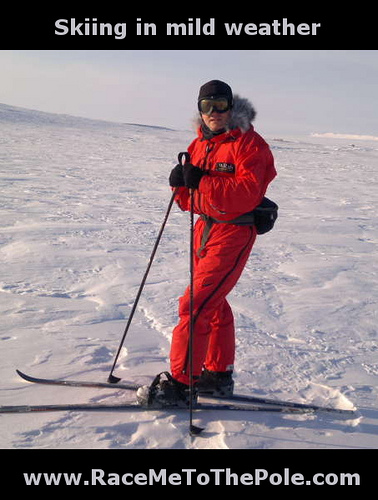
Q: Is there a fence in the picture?
A: No, there are no fences.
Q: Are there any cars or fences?
A: No, there are no fences or cars.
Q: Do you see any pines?
A: No, there are no pines.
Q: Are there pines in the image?
A: No, there are no pines.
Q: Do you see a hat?
A: Yes, there is a hat.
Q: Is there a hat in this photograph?
A: Yes, there is a hat.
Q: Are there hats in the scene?
A: Yes, there is a hat.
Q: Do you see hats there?
A: Yes, there is a hat.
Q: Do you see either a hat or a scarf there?
A: Yes, there is a hat.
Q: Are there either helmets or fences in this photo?
A: No, there are no fences or helmets.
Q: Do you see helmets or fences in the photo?
A: No, there are no fences or helmets.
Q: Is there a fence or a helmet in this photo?
A: No, there are no fences or helmets.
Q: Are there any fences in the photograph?
A: No, there are no fences.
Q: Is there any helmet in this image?
A: No, there are no helmets.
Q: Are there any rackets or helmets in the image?
A: No, there are no helmets or rackets.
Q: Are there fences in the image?
A: No, there are no fences.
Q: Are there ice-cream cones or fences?
A: No, there are no fences or ice-cream cones.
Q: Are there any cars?
A: No, there are no cars.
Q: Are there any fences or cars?
A: No, there are no cars or fences.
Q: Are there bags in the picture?
A: Yes, there is a bag.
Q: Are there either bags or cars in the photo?
A: Yes, there is a bag.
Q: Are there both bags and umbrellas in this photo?
A: No, there is a bag but no umbrellas.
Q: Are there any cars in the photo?
A: No, there are no cars.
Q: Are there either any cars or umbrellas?
A: No, there are no cars or umbrellas.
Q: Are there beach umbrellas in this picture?
A: No, there are no beach umbrellas.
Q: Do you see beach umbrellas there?
A: No, there are no beach umbrellas.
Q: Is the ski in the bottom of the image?
A: Yes, the ski is in the bottom of the image.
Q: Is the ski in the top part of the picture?
A: No, the ski is in the bottom of the image.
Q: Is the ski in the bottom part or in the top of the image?
A: The ski is in the bottom of the image.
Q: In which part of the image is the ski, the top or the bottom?
A: The ski is in the bottom of the image.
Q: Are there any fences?
A: No, there are no fences.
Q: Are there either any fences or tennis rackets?
A: No, there are no fences or tennis rackets.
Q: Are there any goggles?
A: Yes, there are goggles.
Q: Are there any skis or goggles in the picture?
A: Yes, there are goggles.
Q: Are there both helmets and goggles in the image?
A: No, there are goggles but no helmets.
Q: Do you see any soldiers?
A: No, there are no soldiers.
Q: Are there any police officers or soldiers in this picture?
A: No, there are no soldiers or police officers.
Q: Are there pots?
A: No, there are no pots.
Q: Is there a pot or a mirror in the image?
A: No, there are no pots or mirrors.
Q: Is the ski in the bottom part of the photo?
A: Yes, the ski is in the bottom of the image.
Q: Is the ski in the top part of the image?
A: No, the ski is in the bottom of the image.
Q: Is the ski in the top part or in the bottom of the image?
A: The ski is in the bottom of the image.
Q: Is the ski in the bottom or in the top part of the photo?
A: The ski is in the bottom of the image.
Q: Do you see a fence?
A: No, there are no fences.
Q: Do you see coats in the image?
A: Yes, there is a coat.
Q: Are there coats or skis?
A: Yes, there is a coat.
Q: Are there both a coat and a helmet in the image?
A: No, there is a coat but no helmets.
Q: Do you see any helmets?
A: No, there are no helmets.